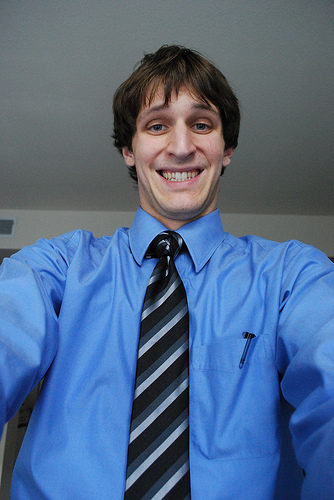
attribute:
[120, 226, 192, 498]
tie — long, striped, stripped , black, gray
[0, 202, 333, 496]
shirt — blue, long sleeve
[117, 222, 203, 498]
tie — black, white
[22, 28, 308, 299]
man — smiling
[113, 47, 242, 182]
hair — short, cut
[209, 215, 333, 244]
wall — white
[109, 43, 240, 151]
hair — shaggy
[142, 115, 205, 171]
nose — large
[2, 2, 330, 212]
ceiling — white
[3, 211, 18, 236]
air vent — white framed